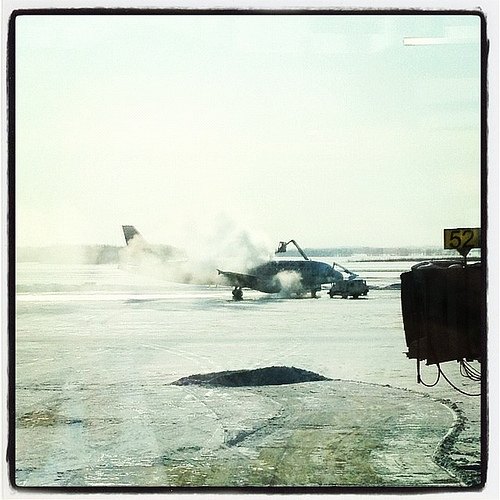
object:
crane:
[275, 239, 309, 261]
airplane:
[120, 223, 345, 303]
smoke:
[122, 232, 272, 278]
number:
[449, 229, 475, 249]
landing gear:
[232, 289, 244, 297]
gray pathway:
[15, 304, 372, 358]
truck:
[327, 279, 371, 299]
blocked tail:
[120, 225, 138, 244]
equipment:
[399, 225, 481, 398]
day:
[18, 16, 479, 484]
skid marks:
[43, 355, 170, 487]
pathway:
[15, 264, 481, 486]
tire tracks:
[217, 374, 462, 449]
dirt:
[172, 365, 328, 386]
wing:
[215, 266, 259, 286]